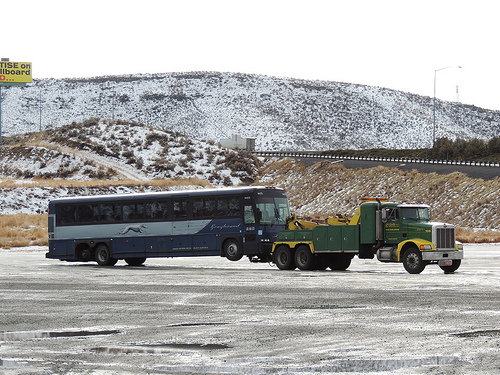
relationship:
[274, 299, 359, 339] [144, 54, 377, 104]
snow on hills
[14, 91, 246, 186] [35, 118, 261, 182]
snow on brush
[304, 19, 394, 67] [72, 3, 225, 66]
clouds are in sky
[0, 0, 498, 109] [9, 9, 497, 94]
clouds are in sky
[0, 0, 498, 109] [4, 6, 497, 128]
clouds are in sky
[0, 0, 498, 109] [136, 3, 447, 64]
clouds are in sky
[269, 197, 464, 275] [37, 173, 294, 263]
tow truck hauling bus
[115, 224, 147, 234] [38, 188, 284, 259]
logo on bus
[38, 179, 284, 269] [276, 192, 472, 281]
bus being pulled by a tow truck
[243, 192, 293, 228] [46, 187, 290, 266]
windshield on bus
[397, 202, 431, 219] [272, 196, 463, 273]
windshield on truck